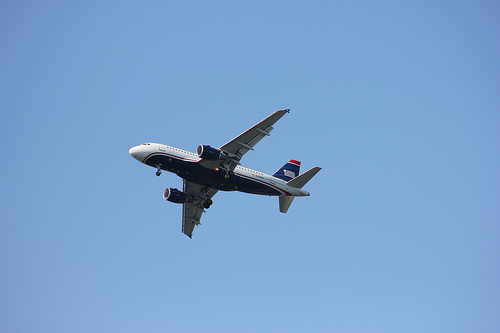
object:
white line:
[191, 144, 221, 156]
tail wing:
[278, 194, 294, 214]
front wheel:
[155, 171, 162, 176]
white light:
[215, 167, 220, 171]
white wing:
[212, 103, 293, 163]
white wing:
[169, 177, 221, 241]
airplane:
[125, 107, 324, 241]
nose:
[128, 144, 144, 159]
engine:
[163, 187, 200, 206]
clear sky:
[0, 0, 498, 331]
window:
[162, 146, 176, 149]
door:
[270, 178, 277, 185]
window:
[147, 143, 151, 148]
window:
[261, 171, 264, 175]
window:
[253, 171, 255, 173]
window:
[239, 167, 241, 169]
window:
[177, 146, 182, 152]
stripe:
[288, 159, 301, 164]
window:
[186, 150, 191, 155]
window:
[242, 168, 244, 170]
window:
[143, 143, 146, 145]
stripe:
[164, 151, 181, 156]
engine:
[194, 141, 225, 162]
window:
[254, 168, 264, 175]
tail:
[285, 166, 325, 189]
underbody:
[148, 152, 282, 197]